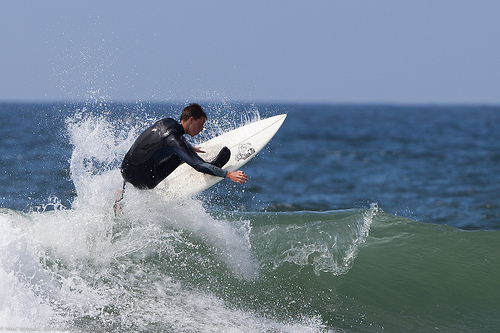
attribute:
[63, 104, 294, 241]
surfboard — white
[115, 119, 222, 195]
wetsuit — black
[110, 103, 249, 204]
surfer — male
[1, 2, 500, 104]
sky — blue, clear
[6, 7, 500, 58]
clouds — white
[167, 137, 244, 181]
arm — extended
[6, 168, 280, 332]
wake — white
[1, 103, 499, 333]
water — blue, dark, calm, white, green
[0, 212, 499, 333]
wave — green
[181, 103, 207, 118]
hair — brown